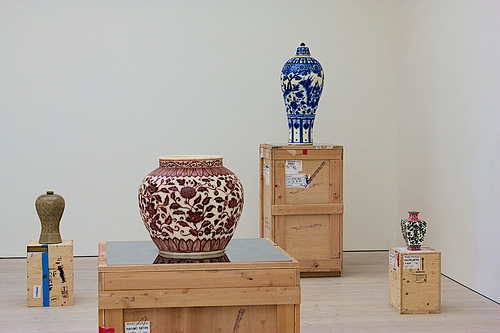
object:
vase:
[281, 41, 324, 145]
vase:
[137, 155, 242, 264]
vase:
[33, 191, 66, 244]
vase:
[400, 210, 427, 251]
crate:
[259, 143, 345, 279]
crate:
[28, 237, 76, 304]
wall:
[1, 2, 403, 258]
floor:
[1, 249, 499, 332]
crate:
[98, 238, 298, 332]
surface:
[99, 237, 299, 266]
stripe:
[42, 244, 49, 307]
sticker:
[286, 174, 311, 188]